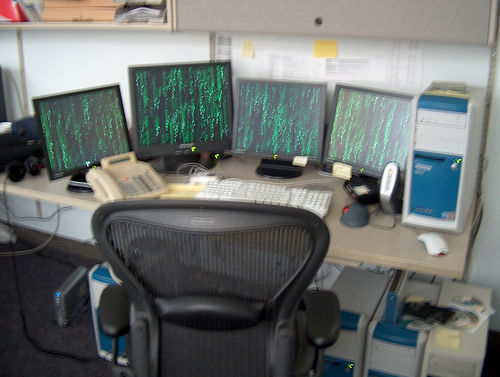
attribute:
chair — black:
[91, 202, 328, 322]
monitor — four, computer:
[29, 69, 411, 178]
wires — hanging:
[28, 205, 52, 251]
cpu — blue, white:
[387, 87, 477, 257]